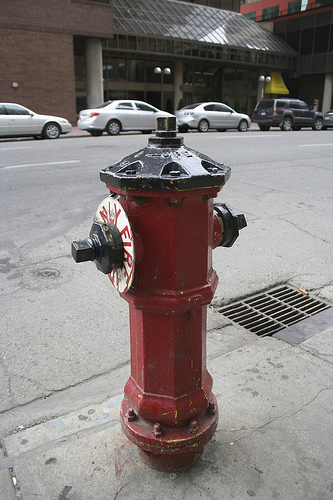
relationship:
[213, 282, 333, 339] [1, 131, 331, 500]
cover on street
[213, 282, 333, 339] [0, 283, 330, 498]
cover on curb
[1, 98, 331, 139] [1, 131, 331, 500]
cars on street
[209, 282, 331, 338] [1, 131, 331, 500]
drain in street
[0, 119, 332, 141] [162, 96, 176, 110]
pedestrian on walkway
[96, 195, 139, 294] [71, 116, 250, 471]
sign on hydrant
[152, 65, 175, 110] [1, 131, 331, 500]
lamp on street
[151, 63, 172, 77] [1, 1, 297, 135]
lights near building